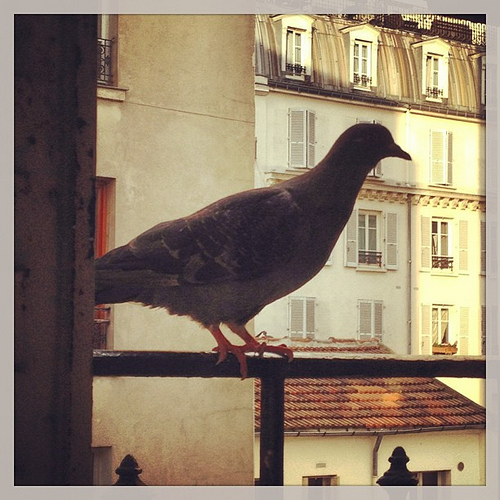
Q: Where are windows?
A: On a building.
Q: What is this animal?
A: Bird.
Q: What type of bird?
A: Pigeon.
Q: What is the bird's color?
A: Gray.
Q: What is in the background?
A: Building.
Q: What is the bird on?
A: Rail.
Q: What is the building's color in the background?
A: White.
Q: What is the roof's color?
A: Reddish brown.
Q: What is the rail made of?
A: Metal.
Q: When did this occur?
A: During the day time.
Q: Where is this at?
A: A balcony.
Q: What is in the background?
A: A building.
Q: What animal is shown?
A: A bird.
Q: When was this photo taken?
A: During the day.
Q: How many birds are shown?
A: One.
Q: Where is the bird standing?
A: On the railing.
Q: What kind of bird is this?
A: Pigeon.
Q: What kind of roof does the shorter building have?
A: Tiled roof.